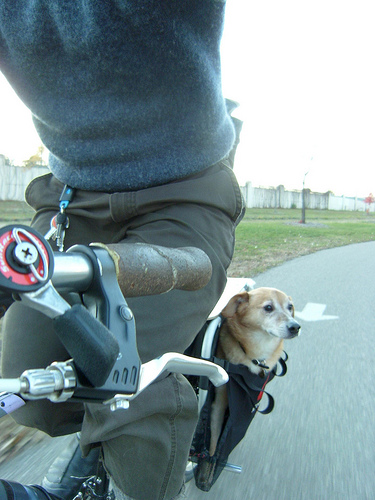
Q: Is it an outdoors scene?
A: Yes, it is outdoors.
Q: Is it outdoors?
A: Yes, it is outdoors.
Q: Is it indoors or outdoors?
A: It is outdoors.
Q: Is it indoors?
A: No, it is outdoors.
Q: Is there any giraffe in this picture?
A: No, there are no giraffes.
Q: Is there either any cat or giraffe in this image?
A: No, there are no giraffes or cats.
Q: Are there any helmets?
A: No, there are no helmets.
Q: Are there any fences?
A: Yes, there is a fence.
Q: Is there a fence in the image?
A: Yes, there is a fence.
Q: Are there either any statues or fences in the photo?
A: Yes, there is a fence.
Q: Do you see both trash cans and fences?
A: No, there is a fence but no trash cans.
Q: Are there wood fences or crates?
A: Yes, there is a wood fence.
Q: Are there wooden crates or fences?
A: Yes, there is a wood fence.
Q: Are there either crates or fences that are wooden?
A: Yes, the fence is wooden.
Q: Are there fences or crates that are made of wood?
A: Yes, the fence is made of wood.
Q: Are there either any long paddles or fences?
A: Yes, there is a long fence.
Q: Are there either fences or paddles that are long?
A: Yes, the fence is long.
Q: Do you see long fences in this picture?
A: Yes, there is a long fence.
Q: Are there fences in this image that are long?
A: Yes, there is a fence that is long.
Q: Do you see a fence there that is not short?
A: Yes, there is a long fence.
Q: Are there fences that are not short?
A: Yes, there is a long fence.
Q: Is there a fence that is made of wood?
A: Yes, there is a fence that is made of wood.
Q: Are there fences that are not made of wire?
A: Yes, there is a fence that is made of wood.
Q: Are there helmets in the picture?
A: No, there are no helmets.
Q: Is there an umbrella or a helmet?
A: No, there are no helmets or umbrellas.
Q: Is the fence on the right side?
A: Yes, the fence is on the right of the image.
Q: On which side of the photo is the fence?
A: The fence is on the right of the image.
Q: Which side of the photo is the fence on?
A: The fence is on the right of the image.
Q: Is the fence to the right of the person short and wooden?
A: No, the fence is wooden but long.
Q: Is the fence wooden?
A: Yes, the fence is wooden.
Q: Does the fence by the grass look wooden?
A: Yes, the fence is wooden.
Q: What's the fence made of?
A: The fence is made of wood.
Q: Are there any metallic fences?
A: No, there is a fence but it is wooden.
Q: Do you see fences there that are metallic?
A: No, there is a fence but it is wooden.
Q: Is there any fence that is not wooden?
A: No, there is a fence but it is wooden.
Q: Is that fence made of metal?
A: No, the fence is made of wood.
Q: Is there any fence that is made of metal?
A: No, there is a fence but it is made of wood.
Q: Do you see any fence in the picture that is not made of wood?
A: No, there is a fence but it is made of wood.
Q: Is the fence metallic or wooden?
A: The fence is wooden.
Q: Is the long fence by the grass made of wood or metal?
A: The fence is made of wood.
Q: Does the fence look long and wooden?
A: Yes, the fence is long and wooden.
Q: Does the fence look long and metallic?
A: No, the fence is long but wooden.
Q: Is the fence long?
A: Yes, the fence is long.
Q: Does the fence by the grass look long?
A: Yes, the fence is long.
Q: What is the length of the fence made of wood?
A: The fence is long.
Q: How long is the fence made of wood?
A: The fence is long.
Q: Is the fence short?
A: No, the fence is long.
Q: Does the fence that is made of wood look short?
A: No, the fence is long.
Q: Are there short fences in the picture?
A: No, there is a fence but it is long.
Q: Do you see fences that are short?
A: No, there is a fence but it is long.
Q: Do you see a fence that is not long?
A: No, there is a fence but it is long.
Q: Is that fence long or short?
A: The fence is long.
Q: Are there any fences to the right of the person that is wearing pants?
A: Yes, there is a fence to the right of the person.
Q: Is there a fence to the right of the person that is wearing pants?
A: Yes, there is a fence to the right of the person.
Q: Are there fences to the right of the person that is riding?
A: Yes, there is a fence to the right of the person.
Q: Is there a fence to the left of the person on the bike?
A: No, the fence is to the right of the person.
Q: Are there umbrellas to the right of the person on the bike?
A: No, there is a fence to the right of the person.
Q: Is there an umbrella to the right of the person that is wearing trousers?
A: No, there is a fence to the right of the person.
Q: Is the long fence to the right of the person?
A: Yes, the fence is to the right of the person.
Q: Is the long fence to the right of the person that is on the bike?
A: Yes, the fence is to the right of the person.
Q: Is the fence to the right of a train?
A: No, the fence is to the right of the person.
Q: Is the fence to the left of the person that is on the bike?
A: No, the fence is to the right of the person.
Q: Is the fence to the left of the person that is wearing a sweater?
A: No, the fence is to the right of the person.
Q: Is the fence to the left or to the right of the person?
A: The fence is to the right of the person.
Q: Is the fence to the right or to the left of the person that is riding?
A: The fence is to the right of the person.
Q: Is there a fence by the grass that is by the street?
A: Yes, there is a fence by the grass.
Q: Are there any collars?
A: Yes, there is a collar.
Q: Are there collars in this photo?
A: Yes, there is a collar.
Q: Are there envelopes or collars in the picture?
A: Yes, there is a collar.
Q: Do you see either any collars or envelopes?
A: Yes, there is a collar.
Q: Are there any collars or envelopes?
A: Yes, there is a collar.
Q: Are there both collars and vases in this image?
A: No, there is a collar but no vases.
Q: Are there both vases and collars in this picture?
A: No, there is a collar but no vases.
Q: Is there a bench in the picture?
A: No, there are no benches.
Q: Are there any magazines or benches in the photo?
A: No, there are no benches or magazines.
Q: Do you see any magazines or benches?
A: No, there are no benches or magazines.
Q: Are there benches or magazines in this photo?
A: No, there are no benches or magazines.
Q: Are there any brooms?
A: No, there are no brooms.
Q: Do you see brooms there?
A: No, there are no brooms.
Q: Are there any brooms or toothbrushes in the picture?
A: No, there are no brooms or toothbrushes.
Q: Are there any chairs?
A: No, there are no chairs.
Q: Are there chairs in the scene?
A: No, there are no chairs.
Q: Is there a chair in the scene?
A: No, there are no chairs.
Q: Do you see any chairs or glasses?
A: No, there are no chairs or glasses.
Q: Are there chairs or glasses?
A: No, there are no chairs or glasses.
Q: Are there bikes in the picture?
A: Yes, there is a bike.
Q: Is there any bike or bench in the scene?
A: Yes, there is a bike.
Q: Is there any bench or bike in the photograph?
A: Yes, there is a bike.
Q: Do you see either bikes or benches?
A: Yes, there is a bike.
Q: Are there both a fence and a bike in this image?
A: Yes, there are both a bike and a fence.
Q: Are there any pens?
A: No, there are no pens.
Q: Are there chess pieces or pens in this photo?
A: No, there are no pens or chess pieces.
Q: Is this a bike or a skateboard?
A: This is a bike.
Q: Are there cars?
A: No, there are no cars.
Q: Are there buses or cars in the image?
A: No, there are no cars or buses.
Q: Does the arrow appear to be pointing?
A: Yes, the arrow is pointing.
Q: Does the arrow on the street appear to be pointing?
A: Yes, the arrow is pointing.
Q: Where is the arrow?
A: The arrow is on the street.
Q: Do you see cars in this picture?
A: No, there are no cars.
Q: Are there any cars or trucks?
A: No, there are no cars or trucks.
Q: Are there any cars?
A: No, there are no cars.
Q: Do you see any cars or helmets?
A: No, there are no cars or helmets.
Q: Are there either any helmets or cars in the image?
A: No, there are no cars or helmets.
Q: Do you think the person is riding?
A: Yes, the person is riding.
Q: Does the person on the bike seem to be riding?
A: Yes, the person is riding.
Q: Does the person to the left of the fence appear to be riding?
A: Yes, the person is riding.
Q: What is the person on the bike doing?
A: The person is riding.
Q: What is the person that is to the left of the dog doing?
A: The person is riding.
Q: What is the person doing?
A: The person is riding.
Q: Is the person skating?
A: No, the person is riding.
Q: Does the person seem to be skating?
A: No, the person is riding.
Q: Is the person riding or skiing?
A: The person is riding.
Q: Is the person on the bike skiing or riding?
A: The person is riding.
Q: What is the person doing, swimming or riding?
A: The person is riding.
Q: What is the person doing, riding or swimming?
A: The person is riding.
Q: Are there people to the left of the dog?
A: Yes, there is a person to the left of the dog.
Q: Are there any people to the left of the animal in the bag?
A: Yes, there is a person to the left of the dog.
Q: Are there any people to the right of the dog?
A: No, the person is to the left of the dog.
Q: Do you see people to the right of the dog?
A: No, the person is to the left of the dog.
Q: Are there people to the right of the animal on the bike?
A: No, the person is to the left of the dog.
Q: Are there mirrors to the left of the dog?
A: No, there is a person to the left of the dog.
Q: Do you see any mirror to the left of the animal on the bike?
A: No, there is a person to the left of the dog.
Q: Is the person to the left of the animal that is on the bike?
A: Yes, the person is to the left of the dog.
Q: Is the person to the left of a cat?
A: No, the person is to the left of the dog.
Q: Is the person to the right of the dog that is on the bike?
A: No, the person is to the left of the dog.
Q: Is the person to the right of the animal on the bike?
A: No, the person is to the left of the dog.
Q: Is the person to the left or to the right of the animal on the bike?
A: The person is to the left of the dog.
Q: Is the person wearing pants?
A: Yes, the person is wearing pants.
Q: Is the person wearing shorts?
A: No, the person is wearing pants.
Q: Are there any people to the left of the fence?
A: Yes, there is a person to the left of the fence.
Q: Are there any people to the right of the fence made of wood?
A: No, the person is to the left of the fence.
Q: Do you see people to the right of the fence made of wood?
A: No, the person is to the left of the fence.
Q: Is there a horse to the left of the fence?
A: No, there is a person to the left of the fence.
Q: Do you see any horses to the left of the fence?
A: No, there is a person to the left of the fence.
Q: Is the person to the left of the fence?
A: Yes, the person is to the left of the fence.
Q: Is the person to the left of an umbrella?
A: No, the person is to the left of the fence.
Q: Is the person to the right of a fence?
A: No, the person is to the left of a fence.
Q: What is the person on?
A: The person is on the bike.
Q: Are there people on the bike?
A: Yes, there is a person on the bike.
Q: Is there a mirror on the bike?
A: No, there is a person on the bike.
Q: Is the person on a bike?
A: Yes, the person is on a bike.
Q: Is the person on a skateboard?
A: No, the person is on a bike.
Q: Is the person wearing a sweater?
A: Yes, the person is wearing a sweater.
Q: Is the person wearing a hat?
A: No, the person is wearing a sweater.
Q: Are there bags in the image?
A: Yes, there is a bag.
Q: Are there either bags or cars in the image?
A: Yes, there is a bag.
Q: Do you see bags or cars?
A: Yes, there is a bag.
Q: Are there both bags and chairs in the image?
A: No, there is a bag but no chairs.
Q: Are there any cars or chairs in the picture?
A: No, there are no chairs or cars.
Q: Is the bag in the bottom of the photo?
A: Yes, the bag is in the bottom of the image.